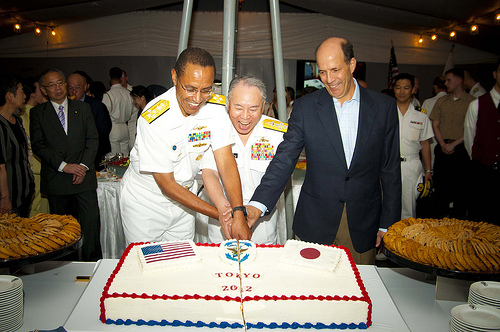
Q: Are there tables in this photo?
A: Yes, there is a table.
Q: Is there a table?
A: Yes, there is a table.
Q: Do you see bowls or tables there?
A: Yes, there is a table.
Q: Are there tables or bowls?
A: Yes, there is a table.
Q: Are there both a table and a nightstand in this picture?
A: No, there is a table but no nightstands.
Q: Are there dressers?
A: No, there are no dressers.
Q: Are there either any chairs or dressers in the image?
A: No, there are no dressers or chairs.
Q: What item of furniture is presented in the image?
A: The piece of furniture is a table.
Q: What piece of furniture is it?
A: The piece of furniture is a table.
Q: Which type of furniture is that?
A: This is a table.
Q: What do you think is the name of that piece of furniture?
A: This is a table.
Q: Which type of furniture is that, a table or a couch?
A: This is a table.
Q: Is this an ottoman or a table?
A: This is a table.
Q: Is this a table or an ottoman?
A: This is a table.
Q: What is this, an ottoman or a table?
A: This is a table.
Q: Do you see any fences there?
A: No, there are no fences.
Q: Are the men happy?
A: Yes, the men are happy.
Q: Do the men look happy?
A: Yes, the men are happy.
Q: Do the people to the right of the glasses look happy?
A: Yes, the men are happy.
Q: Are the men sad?
A: No, the men are happy.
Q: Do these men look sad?
A: No, the men are happy.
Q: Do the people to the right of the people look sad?
A: No, the men are happy.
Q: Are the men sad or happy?
A: The men are happy.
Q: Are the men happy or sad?
A: The men are happy.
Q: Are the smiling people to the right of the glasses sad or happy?
A: The men are happy.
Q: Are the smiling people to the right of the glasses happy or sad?
A: The men are happy.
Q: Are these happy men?
A: Yes, these are happy men.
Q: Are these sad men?
A: No, these are happy men.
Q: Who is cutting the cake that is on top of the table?
A: The men are cutting the cake.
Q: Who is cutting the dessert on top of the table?
A: The men are cutting the cake.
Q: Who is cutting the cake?
A: The men are cutting the cake.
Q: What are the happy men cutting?
A: The men are cutting the cake.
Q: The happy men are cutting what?
A: The men are cutting the cake.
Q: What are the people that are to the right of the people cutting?
A: The men are cutting the cake.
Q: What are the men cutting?
A: The men are cutting the cake.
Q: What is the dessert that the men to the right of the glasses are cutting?
A: The dessert is a cake.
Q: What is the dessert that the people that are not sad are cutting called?
A: The dessert is a cake.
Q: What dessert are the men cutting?
A: The men are cutting the cake.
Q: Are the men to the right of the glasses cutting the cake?
A: Yes, the men are cutting the cake.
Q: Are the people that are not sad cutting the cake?
A: Yes, the men are cutting the cake.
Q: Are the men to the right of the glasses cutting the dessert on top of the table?
A: Yes, the men are cutting the cake.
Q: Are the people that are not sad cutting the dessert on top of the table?
A: Yes, the men are cutting the cake.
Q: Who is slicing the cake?
A: The men are slicing the cake.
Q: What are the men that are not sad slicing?
A: The men are slicing the cake.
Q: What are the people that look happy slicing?
A: The men are slicing the cake.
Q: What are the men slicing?
A: The men are slicing the cake.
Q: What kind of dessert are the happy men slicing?
A: The men are slicing the cake.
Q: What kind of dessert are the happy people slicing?
A: The men are slicing the cake.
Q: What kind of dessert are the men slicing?
A: The men are slicing the cake.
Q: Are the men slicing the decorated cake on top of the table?
A: Yes, the men are slicing the cake.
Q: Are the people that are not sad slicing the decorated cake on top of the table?
A: Yes, the men are slicing the cake.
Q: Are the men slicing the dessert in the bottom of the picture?
A: Yes, the men are slicing the cake.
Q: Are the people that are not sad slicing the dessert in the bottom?
A: Yes, the men are slicing the cake.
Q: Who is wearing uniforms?
A: The men are wearing uniforms.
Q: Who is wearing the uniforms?
A: The men are wearing uniforms.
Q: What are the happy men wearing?
A: The men are wearing uniforms.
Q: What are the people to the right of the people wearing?
A: The men are wearing uniforms.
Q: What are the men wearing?
A: The men are wearing uniforms.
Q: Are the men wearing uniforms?
A: Yes, the men are wearing uniforms.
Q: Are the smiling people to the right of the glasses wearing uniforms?
A: Yes, the men are wearing uniforms.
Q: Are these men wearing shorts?
A: No, the men are wearing uniforms.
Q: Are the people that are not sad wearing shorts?
A: No, the men are wearing uniforms.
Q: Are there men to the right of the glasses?
A: Yes, there are men to the right of the glasses.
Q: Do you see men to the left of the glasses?
A: No, the men are to the right of the glasses.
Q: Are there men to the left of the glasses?
A: No, the men are to the right of the glasses.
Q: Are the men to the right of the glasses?
A: Yes, the men are to the right of the glasses.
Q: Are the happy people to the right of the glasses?
A: Yes, the men are to the right of the glasses.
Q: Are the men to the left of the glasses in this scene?
A: No, the men are to the right of the glasses.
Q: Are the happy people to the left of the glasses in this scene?
A: No, the men are to the right of the glasses.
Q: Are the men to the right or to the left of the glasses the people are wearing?
A: The men are to the right of the glasses.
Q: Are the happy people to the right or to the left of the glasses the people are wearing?
A: The men are to the right of the glasses.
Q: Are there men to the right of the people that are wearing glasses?
A: Yes, there are men to the right of the people.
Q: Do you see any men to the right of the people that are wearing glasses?
A: Yes, there are men to the right of the people.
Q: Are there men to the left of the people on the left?
A: No, the men are to the right of the people.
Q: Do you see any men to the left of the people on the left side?
A: No, the men are to the right of the people.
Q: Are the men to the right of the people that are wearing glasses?
A: Yes, the men are to the right of the people.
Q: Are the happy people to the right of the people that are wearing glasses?
A: Yes, the men are to the right of the people.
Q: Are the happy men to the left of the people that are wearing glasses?
A: No, the men are to the right of the people.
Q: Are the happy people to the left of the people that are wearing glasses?
A: No, the men are to the right of the people.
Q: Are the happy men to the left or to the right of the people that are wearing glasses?
A: The men are to the right of the people.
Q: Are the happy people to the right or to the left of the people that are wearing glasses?
A: The men are to the right of the people.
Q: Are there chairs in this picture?
A: No, there are no chairs.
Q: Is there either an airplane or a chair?
A: No, there are no chairs or airplanes.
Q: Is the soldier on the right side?
A: Yes, the soldier is on the right of the image.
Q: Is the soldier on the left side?
A: No, the soldier is on the right of the image.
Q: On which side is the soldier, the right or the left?
A: The soldier is on the right of the image.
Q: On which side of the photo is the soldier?
A: The soldier is on the right of the image.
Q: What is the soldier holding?
A: The soldier is holding the hat.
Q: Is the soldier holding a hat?
A: Yes, the soldier is holding a hat.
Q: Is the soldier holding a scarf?
A: No, the soldier is holding a hat.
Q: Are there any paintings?
A: No, there are no paintings.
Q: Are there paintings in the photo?
A: No, there are no paintings.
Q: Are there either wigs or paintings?
A: No, there are no paintings or wigs.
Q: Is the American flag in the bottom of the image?
A: Yes, the American flag is in the bottom of the image.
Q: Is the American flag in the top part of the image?
A: No, the American flag is in the bottom of the image.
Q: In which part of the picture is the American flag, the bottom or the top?
A: The American flag is in the bottom of the image.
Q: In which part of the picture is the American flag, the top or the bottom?
A: The American flag is in the bottom of the image.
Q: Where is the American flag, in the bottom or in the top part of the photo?
A: The American flag is in the bottom of the image.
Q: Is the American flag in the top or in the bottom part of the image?
A: The American flag is in the bottom of the image.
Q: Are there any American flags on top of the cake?
A: Yes, there is an American flag on top of the cake.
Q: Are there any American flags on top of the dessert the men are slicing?
A: Yes, there is an American flag on top of the cake.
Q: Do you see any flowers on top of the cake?
A: No, there is an American flag on top of the cake.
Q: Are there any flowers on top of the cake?
A: No, there is an American flag on top of the cake.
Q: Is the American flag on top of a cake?
A: Yes, the American flag is on top of a cake.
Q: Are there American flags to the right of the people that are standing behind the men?
A: Yes, there is an American flag to the right of the people.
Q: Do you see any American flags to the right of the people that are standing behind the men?
A: Yes, there is an American flag to the right of the people.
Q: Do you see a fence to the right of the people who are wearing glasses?
A: No, there is an American flag to the right of the people.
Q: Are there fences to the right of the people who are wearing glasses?
A: No, there is an American flag to the right of the people.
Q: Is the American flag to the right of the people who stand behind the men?
A: Yes, the American flag is to the right of the people.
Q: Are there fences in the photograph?
A: No, there are no fences.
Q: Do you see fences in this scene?
A: No, there are no fences.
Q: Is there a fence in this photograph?
A: No, there are no fences.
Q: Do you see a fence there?
A: No, there are no fences.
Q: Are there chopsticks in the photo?
A: No, there are no chopsticks.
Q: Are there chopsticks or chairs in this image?
A: No, there are no chopsticks or chairs.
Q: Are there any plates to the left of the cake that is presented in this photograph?
A: Yes, there are plates to the left of the cake.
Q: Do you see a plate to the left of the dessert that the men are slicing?
A: Yes, there are plates to the left of the cake.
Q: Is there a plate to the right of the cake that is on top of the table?
A: No, the plates are to the left of the cake.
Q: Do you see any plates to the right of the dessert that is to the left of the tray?
A: No, the plates are to the left of the cake.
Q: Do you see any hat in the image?
A: Yes, there is a hat.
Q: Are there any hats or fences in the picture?
A: Yes, there is a hat.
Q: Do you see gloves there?
A: No, there are no gloves.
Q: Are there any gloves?
A: No, there are no gloves.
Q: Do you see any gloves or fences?
A: No, there are no gloves or fences.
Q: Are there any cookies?
A: Yes, there are cookies.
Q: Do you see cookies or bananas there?
A: Yes, there are cookies.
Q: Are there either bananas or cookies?
A: Yes, there are cookies.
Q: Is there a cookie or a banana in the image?
A: Yes, there are cookies.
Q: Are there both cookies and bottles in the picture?
A: No, there are cookies but no bottles.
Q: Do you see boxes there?
A: No, there are no boxes.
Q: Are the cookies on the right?
A: Yes, the cookies are on the right of the image.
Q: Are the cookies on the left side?
A: No, the cookies are on the right of the image.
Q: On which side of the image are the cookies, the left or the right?
A: The cookies are on the right of the image.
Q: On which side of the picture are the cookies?
A: The cookies are on the right of the image.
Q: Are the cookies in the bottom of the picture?
A: Yes, the cookies are in the bottom of the image.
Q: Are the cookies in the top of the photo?
A: No, the cookies are in the bottom of the image.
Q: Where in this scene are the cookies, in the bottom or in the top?
A: The cookies are in the bottom of the image.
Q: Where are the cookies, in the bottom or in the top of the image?
A: The cookies are in the bottom of the image.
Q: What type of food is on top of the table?
A: The food is cookies.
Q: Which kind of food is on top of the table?
A: The food is cookies.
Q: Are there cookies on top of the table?
A: Yes, there are cookies on top of the table.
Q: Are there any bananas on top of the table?
A: No, there are cookies on top of the table.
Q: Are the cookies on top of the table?
A: Yes, the cookies are on top of the table.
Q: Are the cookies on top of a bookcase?
A: No, the cookies are on top of the table.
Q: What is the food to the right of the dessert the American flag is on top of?
A: The food is cookies.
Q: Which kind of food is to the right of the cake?
A: The food is cookies.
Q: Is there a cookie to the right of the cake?
A: Yes, there are cookies to the right of the cake.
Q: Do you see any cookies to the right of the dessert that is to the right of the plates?
A: Yes, there are cookies to the right of the cake.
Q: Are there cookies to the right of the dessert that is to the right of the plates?
A: Yes, there are cookies to the right of the cake.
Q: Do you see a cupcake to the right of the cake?
A: No, there are cookies to the right of the cake.